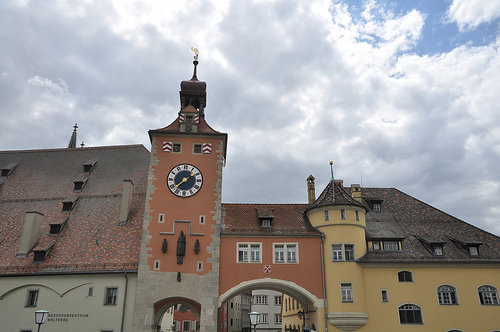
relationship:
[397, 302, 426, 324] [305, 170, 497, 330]
window on building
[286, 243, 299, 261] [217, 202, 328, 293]
window on building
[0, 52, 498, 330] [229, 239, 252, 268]
building has window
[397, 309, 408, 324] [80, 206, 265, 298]
window on building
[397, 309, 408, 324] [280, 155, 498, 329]
window on building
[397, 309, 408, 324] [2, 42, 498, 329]
window on builiding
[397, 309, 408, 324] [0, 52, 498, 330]
window on building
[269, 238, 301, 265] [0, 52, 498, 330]
window on building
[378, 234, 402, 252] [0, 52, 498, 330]
window on building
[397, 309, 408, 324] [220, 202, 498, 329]
window on building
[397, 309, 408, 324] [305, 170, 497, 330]
window on building